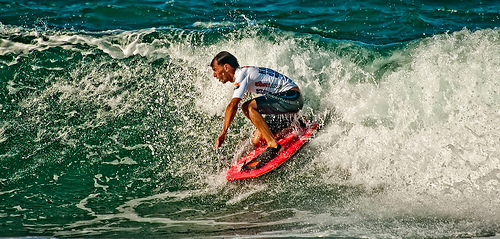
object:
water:
[2, 4, 497, 237]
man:
[207, 49, 306, 165]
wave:
[1, 25, 499, 226]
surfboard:
[227, 115, 332, 180]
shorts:
[256, 89, 303, 115]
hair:
[209, 51, 238, 70]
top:
[227, 66, 303, 99]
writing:
[254, 88, 271, 94]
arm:
[215, 75, 248, 146]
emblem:
[233, 82, 241, 91]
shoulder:
[231, 69, 253, 84]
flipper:
[239, 141, 289, 171]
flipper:
[282, 113, 307, 150]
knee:
[241, 99, 253, 115]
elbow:
[223, 100, 241, 112]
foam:
[195, 30, 490, 213]